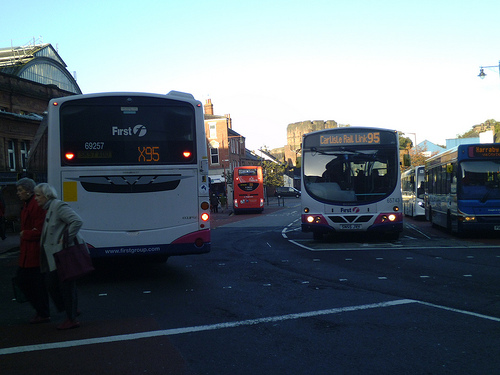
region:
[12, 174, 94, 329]
Two elder women crossing a road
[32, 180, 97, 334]
Woman holding a bag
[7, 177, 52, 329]
Woman wearing a red coat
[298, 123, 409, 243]
White bus stopped at an intersection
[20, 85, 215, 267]
White mass transit bus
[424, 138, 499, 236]
Blue mass transit bus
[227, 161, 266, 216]
Red two level bus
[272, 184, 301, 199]
Black van driving on the road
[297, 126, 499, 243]
Three buses stopped at an intersection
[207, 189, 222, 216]
Person on a sidewalk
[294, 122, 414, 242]
White bus with headlights on.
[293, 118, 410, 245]
Orange digital bus number on screen.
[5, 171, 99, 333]
Elderly women walking across the road.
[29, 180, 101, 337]
Woman in white coat with red bag.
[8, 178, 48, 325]
Woman with red coat and gray hair.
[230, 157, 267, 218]
Red bus picking up passengers.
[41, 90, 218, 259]
White bus with white numbers on window.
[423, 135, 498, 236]
Blue bus with large flat window.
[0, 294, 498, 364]
White lines on the road marking a crosswalk.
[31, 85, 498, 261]
Bus's stopped in marked areas.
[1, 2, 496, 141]
light in daytime sky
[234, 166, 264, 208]
back of red bus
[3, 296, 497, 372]
white lines on asphalt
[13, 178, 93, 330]
two women walking on street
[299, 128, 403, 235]
front of public bus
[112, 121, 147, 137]
logo on bus windows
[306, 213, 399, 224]
two glowing bus headlights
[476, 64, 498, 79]
light on end of pole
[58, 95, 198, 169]
window on back of bus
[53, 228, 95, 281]
purse with handle on arm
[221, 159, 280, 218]
double decker bus on street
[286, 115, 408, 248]
bus on the road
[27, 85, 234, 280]
bus on the road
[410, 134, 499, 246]
buses on the road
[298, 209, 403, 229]
lights on the bus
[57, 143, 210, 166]
lights on the bus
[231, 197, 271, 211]
lights on the bus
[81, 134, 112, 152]
number on the bus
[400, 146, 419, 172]
mirror on the bus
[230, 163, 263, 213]
red bus parked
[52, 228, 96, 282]
black handbag on person's arm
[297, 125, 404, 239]
city bus driving on road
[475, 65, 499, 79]
lamp hanging over road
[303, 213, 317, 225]
headlight on front of bus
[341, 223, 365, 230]
license plate on bus' front bumper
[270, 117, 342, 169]
old brick building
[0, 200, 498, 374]
paved street with lines painted on it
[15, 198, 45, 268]
red jacket on woman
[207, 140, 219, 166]
tall skinny window in building